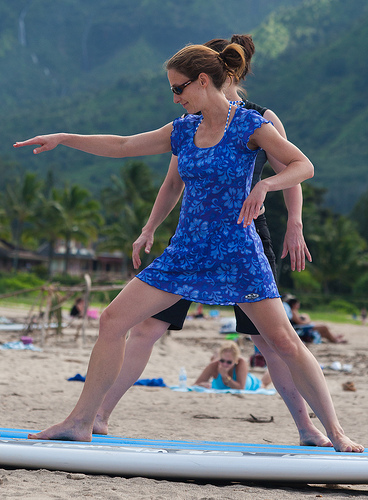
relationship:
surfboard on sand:
[0, 437, 368, 486] [3, 304, 367, 499]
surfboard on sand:
[2, 424, 367, 457] [3, 304, 367, 499]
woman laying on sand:
[195, 343, 273, 391] [3, 304, 367, 499]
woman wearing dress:
[13, 43, 367, 453] [129, 105, 285, 304]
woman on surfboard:
[13, 43, 367, 453] [0, 437, 368, 486]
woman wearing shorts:
[94, 34, 331, 447] [147, 211, 279, 333]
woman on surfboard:
[94, 34, 331, 447] [2, 424, 367, 457]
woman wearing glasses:
[13, 43, 367, 453] [169, 73, 198, 98]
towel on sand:
[65, 371, 166, 388] [3, 304, 367, 499]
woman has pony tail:
[13, 43, 367, 453] [220, 44, 249, 75]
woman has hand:
[13, 43, 367, 453] [13, 129, 63, 155]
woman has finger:
[13, 43, 367, 453] [34, 144, 48, 154]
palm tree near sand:
[46, 179, 100, 280] [3, 304, 367, 499]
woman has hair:
[13, 43, 367, 453] [162, 43, 246, 84]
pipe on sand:
[248, 413, 276, 425] [3, 304, 367, 499]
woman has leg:
[13, 43, 367, 453] [68, 278, 181, 424]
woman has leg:
[13, 43, 367, 453] [236, 300, 346, 434]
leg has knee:
[68, 278, 181, 424] [97, 309, 112, 331]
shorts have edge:
[147, 211, 279, 333] [154, 312, 185, 333]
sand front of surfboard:
[3, 304, 367, 499] [0, 437, 368, 486]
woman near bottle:
[195, 343, 273, 391] [176, 363, 188, 391]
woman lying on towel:
[195, 343, 273, 391] [170, 382, 279, 396]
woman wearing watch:
[195, 343, 273, 391] [223, 372, 235, 388]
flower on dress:
[188, 215, 209, 240] [129, 105, 285, 304]